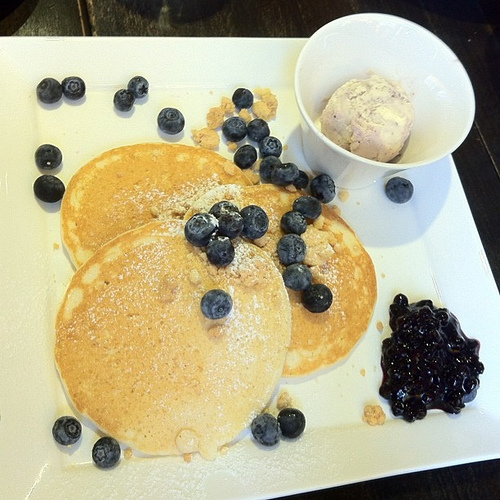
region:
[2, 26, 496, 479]
Food on a plate.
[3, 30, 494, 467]
Breakfast food on a dish.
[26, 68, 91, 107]
Blueberries on a plate.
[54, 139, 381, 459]
Three pancakes on a square plate.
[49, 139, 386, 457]
Pancakes and blueberries on a dish.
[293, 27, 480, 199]
Butter in a cup.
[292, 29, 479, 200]
A white cup filled with butter.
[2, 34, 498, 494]
A white square plate.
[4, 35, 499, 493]
A white plate filled with pancakes and blueberries.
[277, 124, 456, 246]
A shadow on a plate.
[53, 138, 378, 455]
there are three pancakes on the plate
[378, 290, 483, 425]
there is a side of jam on the plate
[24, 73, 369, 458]
the pancakes are sprinkled with blueberries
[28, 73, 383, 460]
this is a plate of blueberry pancakes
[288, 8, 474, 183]
there is a side of butter on the plate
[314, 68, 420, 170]
the butter looks blueberry flavored also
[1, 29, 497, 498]
this plate is square in shape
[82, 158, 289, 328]
there is powdered sugar sprinkled on the pancakes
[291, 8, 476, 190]
the butter is served in a little round bowl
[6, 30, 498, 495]
the serving plate is white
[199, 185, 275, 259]
Blueberry on top of pancakes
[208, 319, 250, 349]
powered sugar on pancakes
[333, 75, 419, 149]
Butter in a bowl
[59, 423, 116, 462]
Blueberries on a plate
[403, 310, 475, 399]
Blueberry jelly on a plate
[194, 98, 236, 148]
Brown sugar on a plate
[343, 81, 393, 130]
butter in a plate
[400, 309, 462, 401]
Blueberry sauce on a plate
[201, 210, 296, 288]
Blueberries and pancakes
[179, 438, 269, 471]
sugar on a plate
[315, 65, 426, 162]
scoop of icecream in white bowl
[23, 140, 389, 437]
pancakes covered in blue berries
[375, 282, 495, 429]
pile of cooked blueberries on side of plate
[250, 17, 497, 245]
white bowl sitting on plate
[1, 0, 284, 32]
black boards on table top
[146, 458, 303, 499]
white powered sugar on plate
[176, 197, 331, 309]
blueberries on top of pancakes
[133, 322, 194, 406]
small holes on top of pancake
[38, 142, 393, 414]
three pancakes and berries on plate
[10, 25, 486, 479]
blueberry pancakes and icecream on plate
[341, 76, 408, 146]
whipped butter in dish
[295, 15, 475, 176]
small white dish on plate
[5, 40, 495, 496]
square shaped white plate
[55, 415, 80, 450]
a blueberry on plate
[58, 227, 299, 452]
pancake on plate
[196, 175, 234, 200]
powdered sugar on pancake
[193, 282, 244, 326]
blueberry on the pancake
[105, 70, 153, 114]
two blueberries on plate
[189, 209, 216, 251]
blueberry with powdered sugar on it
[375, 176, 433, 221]
blueberry on plate near small dish